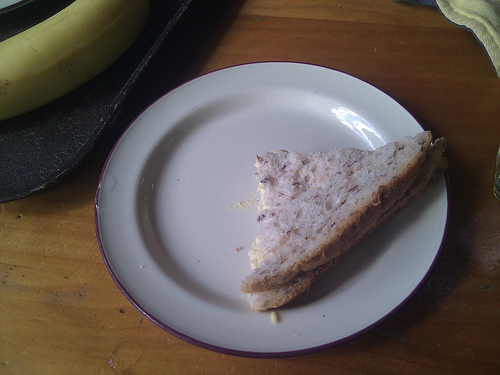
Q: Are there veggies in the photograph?
A: No, there are no veggies.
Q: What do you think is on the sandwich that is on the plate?
A: The eggs are on the sandwich.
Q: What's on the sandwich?
A: The eggs are on the sandwich.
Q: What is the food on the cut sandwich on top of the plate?
A: The food is eggs.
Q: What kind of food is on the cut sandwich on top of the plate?
A: The food is eggs.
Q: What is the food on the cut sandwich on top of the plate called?
A: The food is eggs.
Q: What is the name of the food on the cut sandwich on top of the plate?
A: The food is eggs.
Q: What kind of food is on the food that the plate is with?
A: The food is eggs.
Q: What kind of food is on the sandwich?
A: The food is eggs.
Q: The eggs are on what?
A: The eggs are on the sandwich.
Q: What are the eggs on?
A: The eggs are on the sandwich.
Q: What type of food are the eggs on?
A: The eggs are on the sandwich.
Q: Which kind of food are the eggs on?
A: The eggs are on the sandwich.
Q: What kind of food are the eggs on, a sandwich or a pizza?
A: The eggs are on a sandwich.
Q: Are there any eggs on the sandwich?
A: Yes, there are eggs on the sandwich.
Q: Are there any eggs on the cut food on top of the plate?
A: Yes, there are eggs on the sandwich.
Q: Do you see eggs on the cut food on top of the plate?
A: Yes, there are eggs on the sandwich.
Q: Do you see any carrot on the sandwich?
A: No, there are eggs on the sandwich.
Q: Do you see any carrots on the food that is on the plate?
A: No, there are eggs on the sandwich.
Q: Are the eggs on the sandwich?
A: Yes, the eggs are on the sandwich.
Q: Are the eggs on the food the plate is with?
A: Yes, the eggs are on the sandwich.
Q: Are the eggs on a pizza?
A: No, the eggs are on the sandwich.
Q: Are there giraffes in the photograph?
A: No, there are no giraffes.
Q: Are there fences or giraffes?
A: No, there are no giraffes or fences.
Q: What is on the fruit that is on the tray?
A: The spots are on the banana.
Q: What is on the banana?
A: The spots are on the banana.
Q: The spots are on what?
A: The spots are on the banana.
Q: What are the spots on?
A: The spots are on the banana.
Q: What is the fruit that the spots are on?
A: The fruit is a banana.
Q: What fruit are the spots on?
A: The spots are on the banana.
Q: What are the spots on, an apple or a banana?
A: The spots are on a banana.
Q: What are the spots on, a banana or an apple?
A: The spots are on a banana.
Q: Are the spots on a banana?
A: Yes, the spots are on a banana.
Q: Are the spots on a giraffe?
A: No, the spots are on a banana.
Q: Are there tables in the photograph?
A: Yes, there is a table.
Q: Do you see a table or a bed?
A: Yes, there is a table.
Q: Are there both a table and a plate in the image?
A: Yes, there are both a table and a plate.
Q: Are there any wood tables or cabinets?
A: Yes, there is a wood table.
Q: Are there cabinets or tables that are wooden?
A: Yes, the table is wooden.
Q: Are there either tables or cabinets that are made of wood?
A: Yes, the table is made of wood.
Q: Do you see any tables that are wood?
A: Yes, there is a wood table.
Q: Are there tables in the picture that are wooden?
A: Yes, there is a table that is wooden.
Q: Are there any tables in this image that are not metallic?
A: Yes, there is a wooden table.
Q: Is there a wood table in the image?
A: Yes, there is a table that is made of wood.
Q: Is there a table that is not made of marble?
A: Yes, there is a table that is made of wood.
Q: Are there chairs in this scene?
A: No, there are no chairs.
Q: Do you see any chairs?
A: No, there are no chairs.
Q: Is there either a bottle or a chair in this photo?
A: No, there are no chairs or bottles.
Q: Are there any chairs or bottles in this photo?
A: No, there are no chairs or bottles.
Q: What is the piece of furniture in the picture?
A: The piece of furniture is a table.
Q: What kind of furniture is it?
A: The piece of furniture is a table.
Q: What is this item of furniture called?
A: This is a table.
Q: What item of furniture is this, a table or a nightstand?
A: This is a table.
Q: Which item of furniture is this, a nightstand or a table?
A: This is a table.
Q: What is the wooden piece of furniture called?
A: The piece of furniture is a table.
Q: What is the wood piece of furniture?
A: The piece of furniture is a table.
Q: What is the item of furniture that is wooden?
A: The piece of furniture is a table.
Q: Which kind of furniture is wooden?
A: The furniture is a table.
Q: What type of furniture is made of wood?
A: The furniture is a table.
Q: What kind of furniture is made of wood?
A: The furniture is a table.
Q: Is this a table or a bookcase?
A: This is a table.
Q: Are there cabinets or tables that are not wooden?
A: No, there is a table but it is wooden.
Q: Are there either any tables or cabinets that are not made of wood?
A: No, there is a table but it is made of wood.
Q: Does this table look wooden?
A: Yes, the table is wooden.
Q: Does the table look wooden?
A: Yes, the table is wooden.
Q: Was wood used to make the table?
A: Yes, the table is made of wood.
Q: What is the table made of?
A: The table is made of wood.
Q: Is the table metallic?
A: No, the table is wooden.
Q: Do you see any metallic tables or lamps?
A: No, there is a table but it is wooden.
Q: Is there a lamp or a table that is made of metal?
A: No, there is a table but it is made of wood.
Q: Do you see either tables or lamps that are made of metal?
A: No, there is a table but it is made of wood.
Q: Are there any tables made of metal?
A: No, there is a table but it is made of wood.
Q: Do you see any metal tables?
A: No, there is a table but it is made of wood.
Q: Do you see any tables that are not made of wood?
A: No, there is a table but it is made of wood.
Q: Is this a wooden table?
A: Yes, this is a wooden table.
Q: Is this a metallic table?
A: No, this is a wooden table.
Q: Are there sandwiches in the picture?
A: Yes, there is a sandwich.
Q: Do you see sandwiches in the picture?
A: Yes, there is a sandwich.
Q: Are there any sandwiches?
A: Yes, there is a sandwich.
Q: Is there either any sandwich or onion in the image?
A: Yes, there is a sandwich.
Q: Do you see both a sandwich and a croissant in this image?
A: No, there is a sandwich but no croissants.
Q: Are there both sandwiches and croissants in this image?
A: No, there is a sandwich but no croissants.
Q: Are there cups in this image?
A: No, there are no cups.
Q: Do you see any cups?
A: No, there are no cups.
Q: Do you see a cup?
A: No, there are no cups.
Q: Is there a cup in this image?
A: No, there are no cups.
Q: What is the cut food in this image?
A: The food is a sandwich.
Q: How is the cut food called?
A: The food is a sandwich.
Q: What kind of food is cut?
A: The food is a sandwich.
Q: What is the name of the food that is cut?
A: The food is a sandwich.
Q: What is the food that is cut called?
A: The food is a sandwich.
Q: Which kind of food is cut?
A: The food is a sandwich.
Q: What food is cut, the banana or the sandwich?
A: The sandwich is cut.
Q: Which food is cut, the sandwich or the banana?
A: The sandwich is cut.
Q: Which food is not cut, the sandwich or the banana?
A: The banana is not cut.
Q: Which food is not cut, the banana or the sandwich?
A: The banana is not cut.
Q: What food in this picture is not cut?
A: The food is a banana.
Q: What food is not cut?
A: The food is a banana.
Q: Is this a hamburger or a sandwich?
A: This is a sandwich.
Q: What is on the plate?
A: The sandwich is on the plate.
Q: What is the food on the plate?
A: The food is a sandwich.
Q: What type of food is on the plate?
A: The food is a sandwich.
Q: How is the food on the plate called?
A: The food is a sandwich.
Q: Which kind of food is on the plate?
A: The food is a sandwich.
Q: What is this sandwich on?
A: The sandwich is on the plate.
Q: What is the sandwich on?
A: The sandwich is on the plate.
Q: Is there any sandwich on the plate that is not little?
A: Yes, there is a sandwich on the plate.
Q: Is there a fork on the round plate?
A: No, there is a sandwich on the plate.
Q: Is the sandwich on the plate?
A: Yes, the sandwich is on the plate.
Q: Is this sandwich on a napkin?
A: No, the sandwich is on the plate.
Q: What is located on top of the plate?
A: The sandwich is on top of the plate.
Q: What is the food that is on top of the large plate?
A: The food is a sandwich.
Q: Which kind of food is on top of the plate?
A: The food is a sandwich.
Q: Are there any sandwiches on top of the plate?
A: Yes, there is a sandwich on top of the plate.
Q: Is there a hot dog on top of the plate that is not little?
A: No, there is a sandwich on top of the plate.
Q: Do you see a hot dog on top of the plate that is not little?
A: No, there is a sandwich on top of the plate.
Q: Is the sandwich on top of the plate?
A: Yes, the sandwich is on top of the plate.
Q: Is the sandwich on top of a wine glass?
A: No, the sandwich is on top of the plate.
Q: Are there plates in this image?
A: Yes, there is a plate.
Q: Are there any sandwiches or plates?
A: Yes, there is a plate.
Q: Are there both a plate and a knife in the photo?
A: No, there is a plate but no knives.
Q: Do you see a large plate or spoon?
A: Yes, there is a large plate.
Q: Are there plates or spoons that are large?
A: Yes, the plate is large.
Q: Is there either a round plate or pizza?
A: Yes, there is a round plate.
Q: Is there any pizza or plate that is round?
A: Yes, the plate is round.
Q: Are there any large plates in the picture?
A: Yes, there is a large plate.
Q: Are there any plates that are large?
A: Yes, there is a plate that is large.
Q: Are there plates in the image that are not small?
A: Yes, there is a large plate.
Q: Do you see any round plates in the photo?
A: Yes, there is a round plate.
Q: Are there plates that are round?
A: Yes, there is a plate that is round.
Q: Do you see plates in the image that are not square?
A: Yes, there is a round plate.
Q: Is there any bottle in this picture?
A: No, there are no bottles.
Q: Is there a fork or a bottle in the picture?
A: No, there are no bottles or forks.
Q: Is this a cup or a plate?
A: This is a plate.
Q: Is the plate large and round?
A: Yes, the plate is large and round.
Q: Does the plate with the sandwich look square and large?
A: No, the plate is large but round.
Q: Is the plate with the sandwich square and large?
A: No, the plate is large but round.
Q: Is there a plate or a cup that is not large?
A: No, there is a plate but it is large.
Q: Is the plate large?
A: Yes, the plate is large.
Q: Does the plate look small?
A: No, the plate is large.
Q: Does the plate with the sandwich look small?
A: No, the plate is large.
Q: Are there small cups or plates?
A: No, there is a plate but it is large.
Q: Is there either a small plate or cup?
A: No, there is a plate but it is large.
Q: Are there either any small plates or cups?
A: No, there is a plate but it is large.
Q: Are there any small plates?
A: No, there is a plate but it is large.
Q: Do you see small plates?
A: No, there is a plate but it is large.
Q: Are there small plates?
A: No, there is a plate but it is large.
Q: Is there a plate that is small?
A: No, there is a plate but it is large.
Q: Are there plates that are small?
A: No, there is a plate but it is large.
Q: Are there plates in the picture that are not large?
A: No, there is a plate but it is large.